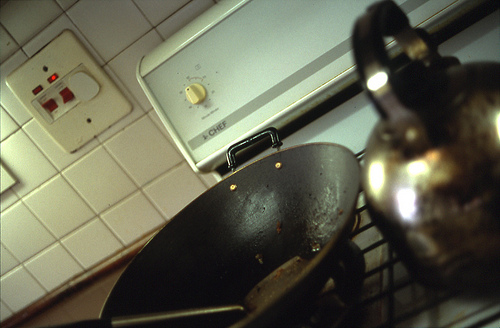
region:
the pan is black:
[128, 180, 338, 317]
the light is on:
[21, 74, 105, 131]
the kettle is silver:
[360, 141, 486, 295]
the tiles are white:
[36, 172, 157, 226]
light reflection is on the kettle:
[356, 173, 448, 235]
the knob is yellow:
[181, 90, 203, 100]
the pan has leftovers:
[195, 201, 335, 269]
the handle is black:
[218, 136, 287, 158]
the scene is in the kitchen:
[4, 6, 498, 322]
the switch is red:
[41, 100, 76, 110]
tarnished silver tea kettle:
[346, 2, 498, 313]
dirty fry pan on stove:
[85, 135, 360, 314]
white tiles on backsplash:
[26, 172, 136, 235]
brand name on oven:
[195, 115, 230, 143]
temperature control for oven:
[177, 65, 218, 115]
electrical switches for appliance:
[28, 54, 110, 154]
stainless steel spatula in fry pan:
[38, 255, 304, 326]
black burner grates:
[349, 226, 434, 320]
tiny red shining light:
[43, 71, 58, 83]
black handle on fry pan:
[220, 122, 284, 178]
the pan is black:
[109, 63, 307, 306]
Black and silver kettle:
[351, 0, 498, 282]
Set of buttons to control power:
[5, 31, 132, 153]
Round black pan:
[100, 130, 360, 321]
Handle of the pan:
[224, 121, 281, 193]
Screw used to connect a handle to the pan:
[225, 181, 242, 195]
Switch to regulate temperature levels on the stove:
[180, 81, 206, 104]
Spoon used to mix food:
[50, 250, 305, 325]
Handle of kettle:
[340, 0, 457, 155]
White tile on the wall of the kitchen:
[21, 173, 92, 243]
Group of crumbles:
[270, 187, 348, 242]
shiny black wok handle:
[220, 126, 291, 173]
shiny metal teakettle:
[338, 3, 498, 313]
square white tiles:
[18, 153, 130, 326]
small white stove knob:
[177, 74, 220, 115]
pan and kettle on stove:
[97, 3, 499, 323]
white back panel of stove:
[129, 1, 371, 183]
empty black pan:
[98, 139, 365, 326]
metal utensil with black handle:
[10, 296, 265, 326]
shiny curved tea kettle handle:
[343, 1, 435, 146]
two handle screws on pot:
[216, 152, 296, 196]